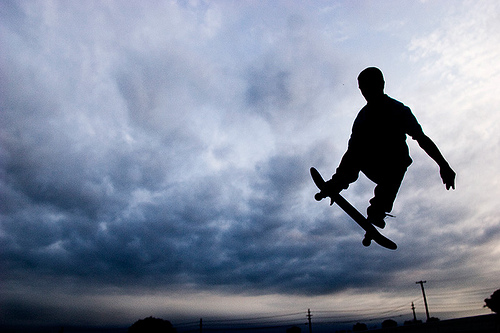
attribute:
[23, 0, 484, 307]
sky — dark, cloudy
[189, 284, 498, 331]
wires — telephone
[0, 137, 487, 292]
grey clouds — dark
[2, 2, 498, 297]
clouds — dark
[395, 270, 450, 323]
pole — tall, telephone pole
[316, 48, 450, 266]
man — silhouette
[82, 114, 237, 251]
clouds — bluish grey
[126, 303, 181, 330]
tree — silhouette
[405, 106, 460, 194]
arm — airborne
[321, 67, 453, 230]
skateboarder — airborne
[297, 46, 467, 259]
young/male skateboarding — young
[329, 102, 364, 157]
sleeve — rolled-up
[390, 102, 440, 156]
sleeve — rolled-up